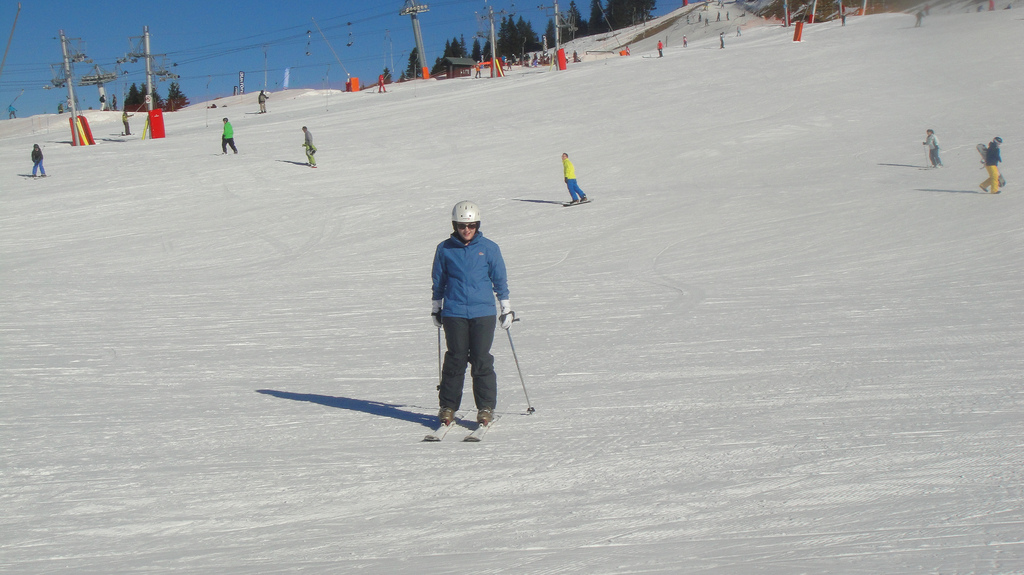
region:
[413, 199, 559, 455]
The nearest skier to the camera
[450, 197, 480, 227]
The helmet of the nearest skier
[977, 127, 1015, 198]
The snowboarder wearing yellow pants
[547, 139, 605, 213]
The snowboarder wearing a yellow jacket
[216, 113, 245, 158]
The snowboarder wearing a green jacket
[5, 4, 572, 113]
The skilift in the background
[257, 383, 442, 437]
The shadow of the nearest skier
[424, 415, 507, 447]
The skis of the nearest person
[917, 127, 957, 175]
The skier next to the person with yellow pants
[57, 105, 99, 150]
The red and yellow pad furthest right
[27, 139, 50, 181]
person standing on snow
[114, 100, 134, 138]
person standing on snow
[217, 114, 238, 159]
person standing on snow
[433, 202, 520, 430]
person standing on snow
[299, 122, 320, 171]
person standing on snow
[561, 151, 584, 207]
person standing on snow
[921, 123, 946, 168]
person standing on snow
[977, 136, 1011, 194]
person standing on snow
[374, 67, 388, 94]
person standing on snow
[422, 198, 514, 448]
person standing on skis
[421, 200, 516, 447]
person wearing a white helmet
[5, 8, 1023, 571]
snow covered hill for skiing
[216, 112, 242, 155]
person wearing a bright green top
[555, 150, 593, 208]
person wearing a bright yellow top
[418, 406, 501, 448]
skis planted in the snow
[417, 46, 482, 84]
small brown building with a gray roof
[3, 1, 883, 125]
ski lift above the snow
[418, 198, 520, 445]
person wearing blue jacket and black pants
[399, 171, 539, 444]
skier on white snow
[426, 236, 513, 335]
blue jacket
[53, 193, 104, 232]
white snow on hill side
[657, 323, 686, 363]
white snow on hill side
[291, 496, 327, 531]
white snow on hill side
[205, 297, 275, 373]
white snow on hill side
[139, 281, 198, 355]
white snow on hill side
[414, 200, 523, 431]
the man is skiing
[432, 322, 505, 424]
the man is wearing pants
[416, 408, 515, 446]
the man is on skis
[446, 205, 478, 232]
the man has a helmet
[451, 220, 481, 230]
the man has glasses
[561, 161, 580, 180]
the person is wearing yellow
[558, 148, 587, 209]
the person is snowboarding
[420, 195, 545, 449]
the person is on the snow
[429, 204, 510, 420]
A person on some snow.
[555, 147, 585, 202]
A person on some snow.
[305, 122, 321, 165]
A person on some snow.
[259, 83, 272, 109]
A person on some snow.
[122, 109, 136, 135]
A person on some snow.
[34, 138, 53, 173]
A person on some snow.